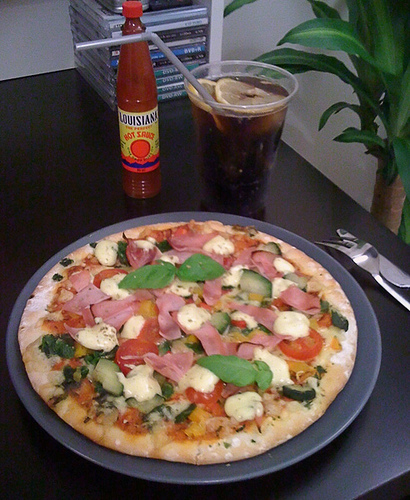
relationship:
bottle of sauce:
[118, 3, 163, 200] [120, 31, 158, 196]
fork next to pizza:
[313, 234, 408, 316] [19, 219, 356, 469]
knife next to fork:
[337, 230, 408, 288] [313, 234, 408, 316]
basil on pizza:
[196, 355, 270, 394] [19, 219, 356, 469]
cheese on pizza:
[276, 312, 311, 343] [19, 219, 356, 469]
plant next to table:
[223, 2, 408, 235] [1, 71, 408, 500]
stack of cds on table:
[69, 0, 208, 110] [1, 71, 408, 500]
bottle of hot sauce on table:
[118, 3, 163, 200] [1, 71, 408, 500]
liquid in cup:
[194, 73, 286, 213] [185, 62, 299, 217]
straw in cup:
[75, 31, 220, 116] [185, 62, 299, 217]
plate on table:
[7, 213, 383, 486] [1, 71, 408, 500]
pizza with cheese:
[19, 219, 356, 469] [276, 312, 311, 343]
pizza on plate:
[19, 219, 356, 469] [7, 213, 383, 486]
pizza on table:
[19, 219, 356, 469] [1, 71, 408, 500]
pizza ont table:
[19, 219, 356, 469] [1, 71, 408, 500]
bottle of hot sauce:
[118, 3, 163, 200] [120, 31, 158, 196]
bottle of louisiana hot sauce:
[118, 3, 163, 200] [120, 31, 158, 196]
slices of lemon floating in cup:
[190, 76, 289, 113] [185, 62, 299, 217]